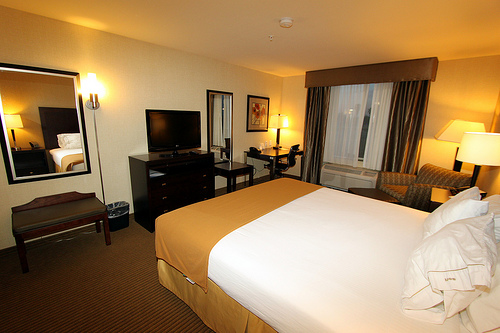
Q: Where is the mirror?
A: On the wall.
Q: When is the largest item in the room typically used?
A: Night.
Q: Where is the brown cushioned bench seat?
A: Under the mirror.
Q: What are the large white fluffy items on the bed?
A: Pillows.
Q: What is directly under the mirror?
A: Bench.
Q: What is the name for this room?
A: Bedroom.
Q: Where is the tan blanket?
A: Foot of the bed.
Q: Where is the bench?
A: Under the mirror.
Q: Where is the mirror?
A: Above the bench.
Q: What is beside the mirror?
A: A lamp.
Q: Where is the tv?
A: On the dresser.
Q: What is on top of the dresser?
A: A tv.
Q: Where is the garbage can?
A: Beside the bench.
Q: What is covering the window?
A: Curtains.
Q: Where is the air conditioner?
A: Under the window.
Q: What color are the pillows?
A: White.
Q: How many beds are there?
A: One.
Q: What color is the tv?
A: Black.